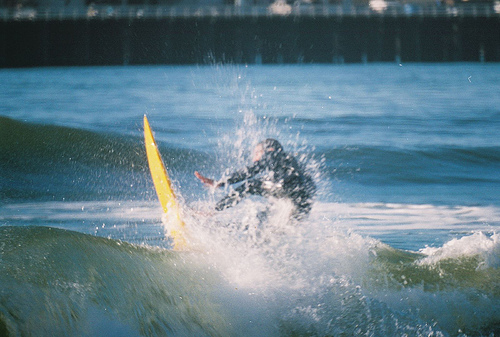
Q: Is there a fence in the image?
A: No, there are no fences.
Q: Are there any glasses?
A: No, there are no glasses.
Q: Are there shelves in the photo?
A: No, there are no shelves.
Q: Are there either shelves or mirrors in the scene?
A: No, there are no shelves or mirrors.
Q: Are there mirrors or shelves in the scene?
A: No, there are no shelves or mirrors.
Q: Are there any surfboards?
A: Yes, there is a surfboard.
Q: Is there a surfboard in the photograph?
A: Yes, there is a surfboard.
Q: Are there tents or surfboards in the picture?
A: Yes, there is a surfboard.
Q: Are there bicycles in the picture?
A: No, there are no bicycles.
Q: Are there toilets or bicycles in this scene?
A: No, there are no bicycles or toilets.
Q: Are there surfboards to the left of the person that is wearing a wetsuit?
A: Yes, there is a surfboard to the left of the person.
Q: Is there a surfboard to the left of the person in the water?
A: Yes, there is a surfboard to the left of the person.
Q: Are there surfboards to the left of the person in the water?
A: Yes, there is a surfboard to the left of the person.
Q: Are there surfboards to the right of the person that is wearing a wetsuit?
A: No, the surfboard is to the left of the person.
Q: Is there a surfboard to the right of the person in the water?
A: No, the surfboard is to the left of the person.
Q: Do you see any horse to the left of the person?
A: No, there is a surfboard to the left of the person.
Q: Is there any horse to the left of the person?
A: No, there is a surfboard to the left of the person.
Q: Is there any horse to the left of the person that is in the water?
A: No, there is a surfboard to the left of the person.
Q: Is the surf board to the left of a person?
A: Yes, the surf board is to the left of a person.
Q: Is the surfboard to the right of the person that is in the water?
A: No, the surfboard is to the left of the person.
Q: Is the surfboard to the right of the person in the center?
A: No, the surfboard is to the left of the person.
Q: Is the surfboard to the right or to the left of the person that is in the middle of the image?
A: The surfboard is to the left of the person.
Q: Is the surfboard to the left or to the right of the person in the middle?
A: The surfboard is to the left of the person.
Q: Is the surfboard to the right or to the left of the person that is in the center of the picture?
A: The surfboard is to the left of the person.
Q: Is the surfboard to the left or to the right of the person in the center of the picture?
A: The surfboard is to the left of the person.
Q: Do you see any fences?
A: No, there are no fences.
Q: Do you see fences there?
A: No, there are no fences.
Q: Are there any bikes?
A: No, there are no bikes.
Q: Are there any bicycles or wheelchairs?
A: No, there are no bicycles or wheelchairs.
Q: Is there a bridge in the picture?
A: Yes, there is a bridge.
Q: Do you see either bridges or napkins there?
A: Yes, there is a bridge.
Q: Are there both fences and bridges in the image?
A: No, there is a bridge but no fences.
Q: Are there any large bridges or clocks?
A: Yes, there is a large bridge.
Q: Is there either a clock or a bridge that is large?
A: Yes, the bridge is large.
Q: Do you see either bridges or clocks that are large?
A: Yes, the bridge is large.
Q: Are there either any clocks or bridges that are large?
A: Yes, the bridge is large.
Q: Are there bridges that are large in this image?
A: Yes, there is a large bridge.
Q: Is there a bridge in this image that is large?
A: Yes, there is a bridge that is large.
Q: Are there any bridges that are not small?
A: Yes, there is a large bridge.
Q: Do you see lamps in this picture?
A: No, there are no lamps.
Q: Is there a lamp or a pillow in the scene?
A: No, there are no lamps or pillows.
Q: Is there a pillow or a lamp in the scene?
A: No, there are no lamps or pillows.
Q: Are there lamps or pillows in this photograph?
A: No, there are no lamps or pillows.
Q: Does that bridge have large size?
A: Yes, the bridge is large.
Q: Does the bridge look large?
A: Yes, the bridge is large.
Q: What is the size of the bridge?
A: The bridge is large.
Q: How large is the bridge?
A: The bridge is large.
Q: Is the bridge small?
A: No, the bridge is large.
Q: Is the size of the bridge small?
A: No, the bridge is large.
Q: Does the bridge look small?
A: No, the bridge is large.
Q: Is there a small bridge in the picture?
A: No, there is a bridge but it is large.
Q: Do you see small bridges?
A: No, there is a bridge but it is large.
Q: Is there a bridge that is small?
A: No, there is a bridge but it is large.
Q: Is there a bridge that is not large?
A: No, there is a bridge but it is large.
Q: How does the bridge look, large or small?
A: The bridge is large.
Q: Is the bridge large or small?
A: The bridge is large.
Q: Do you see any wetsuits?
A: Yes, there is a wetsuit.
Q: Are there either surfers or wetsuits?
A: Yes, there is a wetsuit.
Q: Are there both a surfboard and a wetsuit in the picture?
A: Yes, there are both a wetsuit and a surfboard.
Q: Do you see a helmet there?
A: No, there are no helmets.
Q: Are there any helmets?
A: No, there are no helmets.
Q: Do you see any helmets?
A: No, there are no helmets.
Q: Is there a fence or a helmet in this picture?
A: No, there are no helmets or fences.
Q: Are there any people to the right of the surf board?
A: Yes, there is a person to the right of the surf board.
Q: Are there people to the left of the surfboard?
A: No, the person is to the right of the surfboard.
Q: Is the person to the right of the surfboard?
A: Yes, the person is to the right of the surfboard.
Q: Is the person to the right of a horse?
A: No, the person is to the right of the surfboard.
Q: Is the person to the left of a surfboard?
A: No, the person is to the right of a surfboard.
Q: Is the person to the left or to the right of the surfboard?
A: The person is to the right of the surfboard.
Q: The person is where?
A: The person is in the water.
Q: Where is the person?
A: The person is in the water.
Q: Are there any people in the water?
A: Yes, there is a person in the water.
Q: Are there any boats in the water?
A: No, there is a person in the water.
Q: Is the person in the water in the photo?
A: Yes, the person is in the water.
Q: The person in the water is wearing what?
A: The person is wearing a wetsuit.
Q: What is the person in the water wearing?
A: The person is wearing a wetsuit.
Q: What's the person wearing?
A: The person is wearing a wetsuit.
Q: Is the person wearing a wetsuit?
A: Yes, the person is wearing a wetsuit.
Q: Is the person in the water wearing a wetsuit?
A: Yes, the person is wearing a wetsuit.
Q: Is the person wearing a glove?
A: No, the person is wearing a wetsuit.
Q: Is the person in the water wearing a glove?
A: No, the person is wearing a wetsuit.